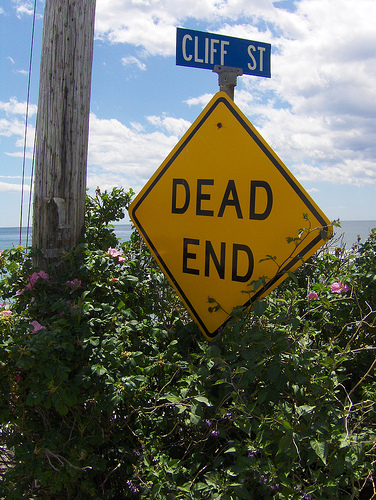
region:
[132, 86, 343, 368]
a yellow rhombus sign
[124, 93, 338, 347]
sign has black border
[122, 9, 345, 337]
a blue sign on top a rhombus sign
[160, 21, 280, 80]
blue sign is rectangle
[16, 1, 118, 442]
a pole on side a yellow sign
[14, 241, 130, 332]
pink flowers around a pole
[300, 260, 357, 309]
pink flowers behind a yellow sign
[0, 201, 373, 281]
the ocean behind a sign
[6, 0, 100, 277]
wires next a pole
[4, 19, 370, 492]
a sign in a bush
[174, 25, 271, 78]
a blue street sign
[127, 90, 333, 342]
yellow and black road sign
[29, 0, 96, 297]
telephone pole beside sign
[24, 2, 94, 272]
telephone pole is wooden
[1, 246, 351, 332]
pink flower blooms in bushes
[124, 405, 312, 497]
purple flowers on bushes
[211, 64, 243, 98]
grey metal pole holding signs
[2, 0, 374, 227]
sky is blue and cloudy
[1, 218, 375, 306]
blue ocean water in distance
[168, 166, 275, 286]
sign says DEAD END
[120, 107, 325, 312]
yellow sign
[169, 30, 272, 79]
blue sign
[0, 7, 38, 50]
white clouds in blue sky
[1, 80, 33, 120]
white clouds in blue sky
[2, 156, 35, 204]
white clouds in blue sky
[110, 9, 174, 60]
white clouds in blue sky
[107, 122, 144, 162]
white clouds in blue sky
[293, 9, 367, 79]
white clouds in blue sky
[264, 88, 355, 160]
white clouds in blue sky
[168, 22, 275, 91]
blue and white lettered street sign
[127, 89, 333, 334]
yellow with black letters and border traffic sign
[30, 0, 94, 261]
utility pole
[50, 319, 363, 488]
green shrubbery under signs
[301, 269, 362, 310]
pink flowers in green bushed near traffic signs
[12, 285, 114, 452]
shadow of utility pole and flowers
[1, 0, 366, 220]
blue and white clouded sky above scene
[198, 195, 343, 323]
ends of green bushed in front of yellow sign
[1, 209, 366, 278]
blue ocean in the background of photo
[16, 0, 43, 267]
wire running up the side of the utility pole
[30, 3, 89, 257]
Wooden utility pole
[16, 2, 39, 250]
Metal wire pole support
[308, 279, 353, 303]
Small pink flowers on bush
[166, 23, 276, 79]
Blue and white street sign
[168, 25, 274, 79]
Cliff street identification sign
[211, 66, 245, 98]
Top of metal sign post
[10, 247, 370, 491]
Green bushes along road side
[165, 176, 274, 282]
Black letters on traffic sign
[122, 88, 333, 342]
Diamond shaped Dead End sign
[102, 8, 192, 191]
Clouds in the sky